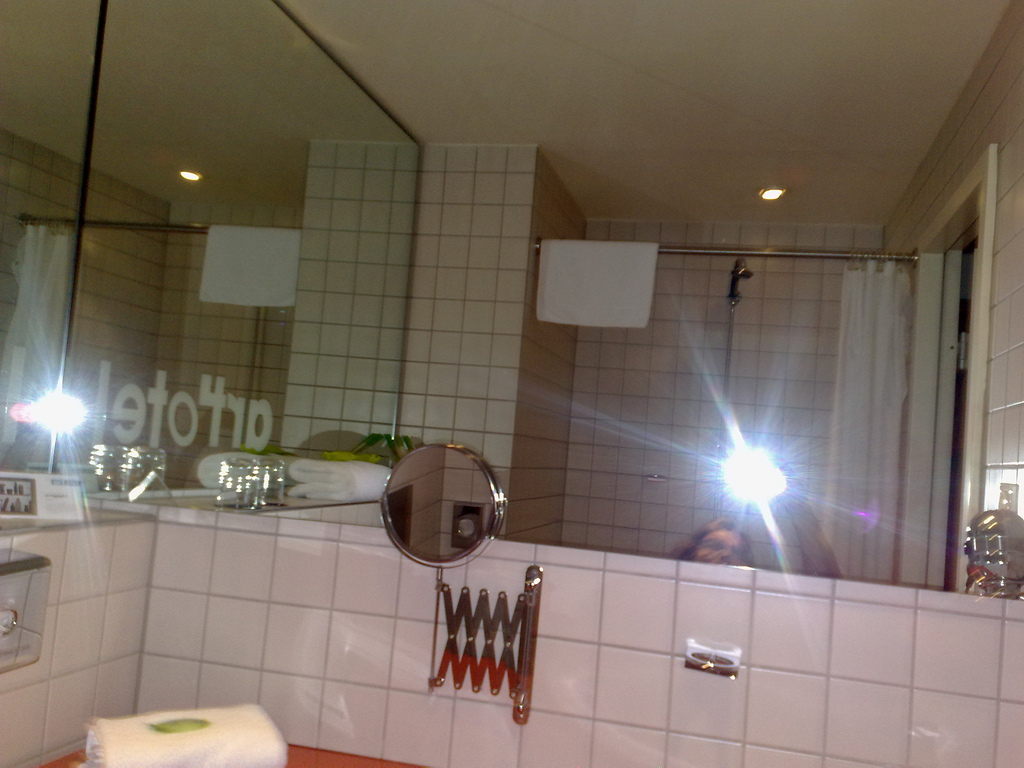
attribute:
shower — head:
[718, 253, 760, 308]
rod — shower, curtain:
[539, 234, 922, 267]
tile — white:
[200, 564, 343, 677]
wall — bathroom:
[172, 519, 393, 738]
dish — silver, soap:
[673, 627, 749, 680]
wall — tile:
[573, 553, 861, 765]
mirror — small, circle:
[383, 435, 505, 563]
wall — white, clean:
[154, 510, 852, 761]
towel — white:
[534, 234, 656, 328]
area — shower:
[573, 214, 924, 564]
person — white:
[673, 513, 779, 563]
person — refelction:
[677, 515, 794, 580]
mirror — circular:
[371, 443, 508, 571]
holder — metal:
[410, 565, 542, 734]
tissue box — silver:
[0, 547, 50, 681]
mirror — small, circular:
[367, 433, 512, 572]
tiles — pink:
[194, 586, 396, 693]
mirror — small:
[375, 446, 509, 555]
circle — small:
[751, 182, 795, 204]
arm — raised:
[780, 495, 822, 552]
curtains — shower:
[815, 290, 917, 567]